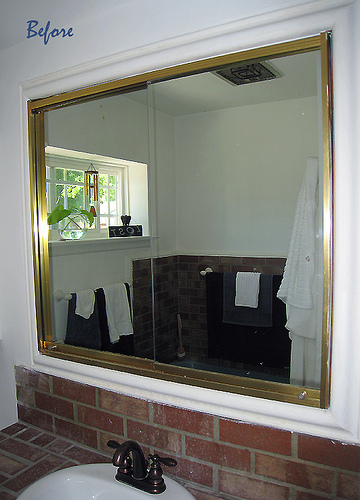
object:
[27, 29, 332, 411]
mirror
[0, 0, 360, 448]
wall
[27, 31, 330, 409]
golden border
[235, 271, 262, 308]
towel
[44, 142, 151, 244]
window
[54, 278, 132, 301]
rack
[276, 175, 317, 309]
bath cloth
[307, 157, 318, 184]
hanger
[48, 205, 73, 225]
leaf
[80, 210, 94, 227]
leaf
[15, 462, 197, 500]
sink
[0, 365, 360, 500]
counter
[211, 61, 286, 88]
extractor fan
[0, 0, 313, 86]
ceiling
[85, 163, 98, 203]
wind chimes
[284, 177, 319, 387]
bathrobe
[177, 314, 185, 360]
reflection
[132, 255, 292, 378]
wall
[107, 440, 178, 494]
fixture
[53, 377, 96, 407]
brick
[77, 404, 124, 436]
brick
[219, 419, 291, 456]
brick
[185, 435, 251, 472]
brick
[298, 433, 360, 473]
brick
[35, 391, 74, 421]
brick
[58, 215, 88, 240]
bowl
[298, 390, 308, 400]
screw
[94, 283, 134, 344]
towel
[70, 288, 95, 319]
towel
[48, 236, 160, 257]
edge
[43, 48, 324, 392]
reflection of room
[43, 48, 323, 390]
glass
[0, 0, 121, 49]
roof